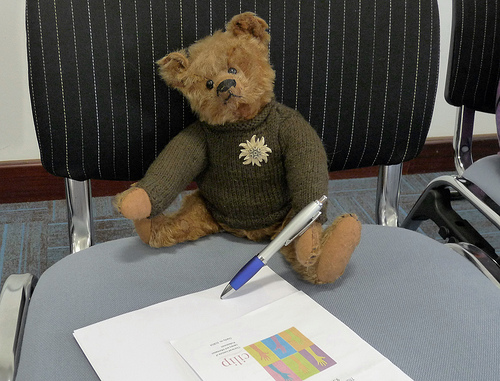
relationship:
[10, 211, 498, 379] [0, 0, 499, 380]
cushion on chair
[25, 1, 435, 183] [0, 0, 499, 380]
back of chair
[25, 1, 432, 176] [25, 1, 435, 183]
stripes on back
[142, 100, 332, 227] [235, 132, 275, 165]
sweater has design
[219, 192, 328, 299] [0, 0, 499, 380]
pen on chair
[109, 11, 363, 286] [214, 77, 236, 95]
bear has nose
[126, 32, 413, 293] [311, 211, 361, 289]
bear has foot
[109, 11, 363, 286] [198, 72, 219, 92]
bear has eye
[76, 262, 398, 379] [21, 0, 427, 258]
papers laying in chair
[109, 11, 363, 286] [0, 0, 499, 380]
bear on chair